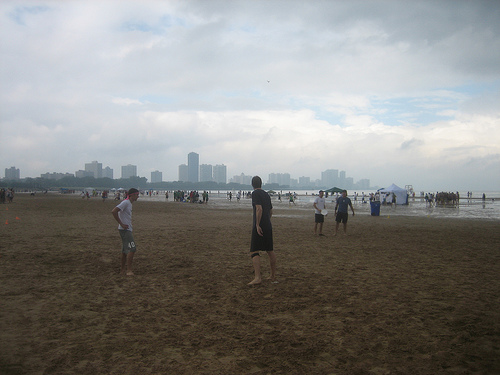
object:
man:
[311, 189, 329, 237]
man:
[108, 185, 141, 276]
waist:
[118, 224, 134, 231]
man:
[242, 172, 281, 285]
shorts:
[246, 225, 281, 256]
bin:
[370, 199, 384, 217]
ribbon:
[127, 189, 139, 194]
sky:
[0, 0, 499, 191]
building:
[186, 150, 203, 185]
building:
[198, 163, 214, 185]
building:
[213, 161, 229, 185]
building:
[177, 162, 189, 183]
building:
[119, 162, 137, 181]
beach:
[0, 184, 499, 374]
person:
[331, 187, 359, 237]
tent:
[368, 175, 416, 208]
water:
[160, 186, 498, 202]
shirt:
[110, 198, 136, 233]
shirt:
[250, 188, 276, 231]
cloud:
[256, 109, 498, 164]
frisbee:
[320, 209, 329, 217]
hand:
[318, 207, 323, 212]